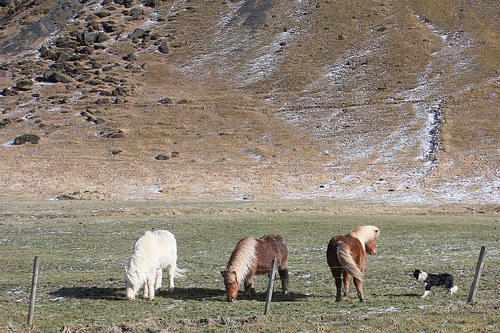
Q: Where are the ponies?
A: Fenced in.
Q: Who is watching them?
A: The dog.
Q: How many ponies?
A: 3.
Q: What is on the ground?
A: Grass.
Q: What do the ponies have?
A: Hair.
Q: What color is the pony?
A: White.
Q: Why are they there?
A: Eating.